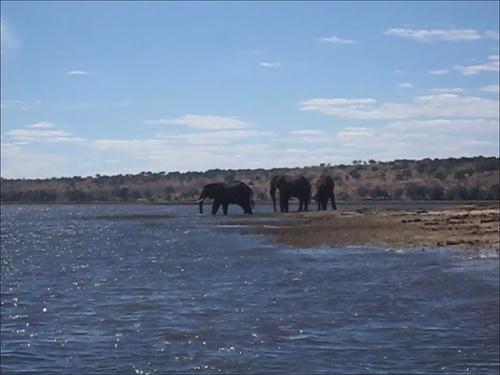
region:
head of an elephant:
[189, 173, 219, 208]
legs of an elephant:
[207, 206, 259, 221]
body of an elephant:
[209, 178, 261, 208]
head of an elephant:
[267, 172, 282, 194]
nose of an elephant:
[263, 188, 280, 213]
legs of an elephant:
[279, 192, 310, 213]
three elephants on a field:
[186, 168, 353, 220]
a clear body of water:
[63, 246, 257, 358]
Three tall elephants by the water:
[192, 170, 336, 217]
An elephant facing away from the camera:
[315, 170, 342, 212]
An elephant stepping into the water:
[195, 180, 258, 219]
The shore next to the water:
[238, 199, 498, 249]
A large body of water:
[1, 200, 498, 373]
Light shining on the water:
[5, 209, 362, 370]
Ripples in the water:
[4, 226, 490, 373]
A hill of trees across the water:
[0, 155, 496, 202]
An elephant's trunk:
[268, 193, 280, 216]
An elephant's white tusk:
[195, 196, 207, 203]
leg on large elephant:
[204, 194, 219, 214]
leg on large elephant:
[218, 198, 232, 220]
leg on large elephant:
[236, 197, 256, 219]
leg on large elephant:
[273, 190, 292, 217]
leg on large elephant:
[312, 185, 329, 212]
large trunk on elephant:
[192, 190, 206, 213]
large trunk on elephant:
[263, 178, 289, 215]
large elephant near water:
[186, 165, 260, 220]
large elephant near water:
[258, 156, 316, 222]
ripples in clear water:
[159, 223, 221, 285]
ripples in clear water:
[192, 299, 257, 350]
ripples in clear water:
[103, 291, 151, 331]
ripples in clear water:
[12, 301, 64, 352]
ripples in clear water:
[10, 245, 49, 287]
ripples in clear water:
[17, 199, 65, 253]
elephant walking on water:
[185, 173, 257, 226]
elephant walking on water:
[263, 165, 318, 218]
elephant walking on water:
[312, 157, 343, 217]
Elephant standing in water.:
[195, 180, 255, 216]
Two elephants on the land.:
[270, 170, 335, 210]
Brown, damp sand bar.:
[286, 210, 496, 240]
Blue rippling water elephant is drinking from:
[0, 242, 495, 364]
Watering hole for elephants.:
[0, 202, 486, 368]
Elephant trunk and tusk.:
[195, 183, 206, 216]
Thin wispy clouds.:
[3, 95, 498, 155]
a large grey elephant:
[193, 174, 259, 217]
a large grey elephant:
[264, 171, 314, 211]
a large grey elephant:
[307, 167, 337, 212]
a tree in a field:
[404, 180, 422, 200]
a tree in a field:
[424, 180, 441, 200]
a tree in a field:
[444, 174, 463, 201]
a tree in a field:
[118, 182, 132, 198]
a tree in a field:
[348, 164, 358, 177]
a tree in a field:
[398, 164, 410, 178]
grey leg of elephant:
[210, 198, 222, 213]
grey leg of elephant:
[219, 203, 229, 218]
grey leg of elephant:
[239, 195, 255, 218]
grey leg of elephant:
[278, 189, 283, 214]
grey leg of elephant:
[283, 200, 288, 211]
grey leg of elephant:
[295, 198, 305, 210]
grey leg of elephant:
[301, 198, 308, 209]